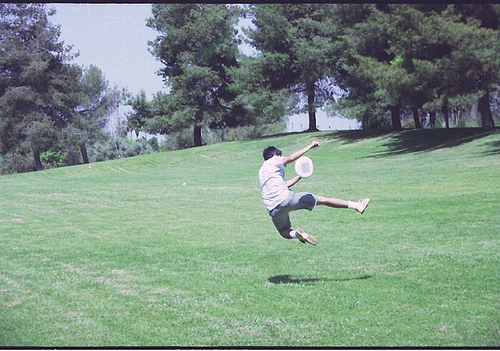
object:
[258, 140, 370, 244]
boy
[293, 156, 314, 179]
frisbee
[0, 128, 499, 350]
grass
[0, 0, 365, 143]
sky